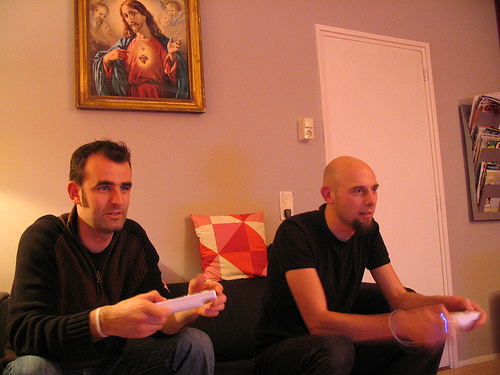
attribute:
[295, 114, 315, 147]
thermostat — white